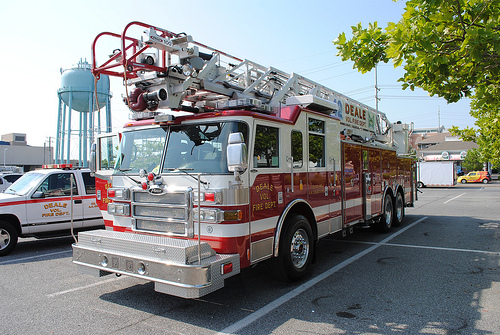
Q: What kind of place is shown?
A: It is a parking lot.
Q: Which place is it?
A: It is a parking lot.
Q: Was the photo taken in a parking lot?
A: Yes, it was taken in a parking lot.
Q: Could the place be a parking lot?
A: Yes, it is a parking lot.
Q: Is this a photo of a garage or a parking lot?
A: It is showing a parking lot.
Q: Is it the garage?
A: No, it is the parking lot.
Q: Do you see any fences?
A: No, there are no fences.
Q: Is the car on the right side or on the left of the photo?
A: The car is on the right of the image.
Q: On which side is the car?
A: The car is on the right of the image.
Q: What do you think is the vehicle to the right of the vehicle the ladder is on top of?
A: The vehicle is a car.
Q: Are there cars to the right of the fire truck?
A: Yes, there is a car to the right of the fire truck.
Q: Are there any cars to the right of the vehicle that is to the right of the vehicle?
A: Yes, there is a car to the right of the fire truck.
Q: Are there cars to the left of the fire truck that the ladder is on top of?
A: No, the car is to the right of the fire truck.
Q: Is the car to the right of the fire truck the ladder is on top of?
A: Yes, the car is to the right of the fire truck.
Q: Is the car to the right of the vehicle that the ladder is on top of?
A: Yes, the car is to the right of the fire truck.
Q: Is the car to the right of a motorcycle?
A: No, the car is to the right of the fire truck.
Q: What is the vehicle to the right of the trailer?
A: The vehicle is a car.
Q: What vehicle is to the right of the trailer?
A: The vehicle is a car.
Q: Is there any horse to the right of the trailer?
A: No, there is a car to the right of the trailer.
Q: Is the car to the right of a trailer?
A: Yes, the car is to the right of a trailer.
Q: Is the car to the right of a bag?
A: No, the car is to the right of a trailer.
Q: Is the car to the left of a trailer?
A: No, the car is to the right of a trailer.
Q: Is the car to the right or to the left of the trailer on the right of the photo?
A: The car is to the right of the trailer.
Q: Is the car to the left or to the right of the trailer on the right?
A: The car is to the right of the trailer.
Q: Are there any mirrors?
A: Yes, there is a mirror.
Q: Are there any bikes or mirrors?
A: Yes, there is a mirror.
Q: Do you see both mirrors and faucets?
A: No, there is a mirror but no faucets.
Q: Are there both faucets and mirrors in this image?
A: No, there is a mirror but no faucets.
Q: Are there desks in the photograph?
A: No, there are no desks.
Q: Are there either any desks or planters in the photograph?
A: No, there are no desks or planters.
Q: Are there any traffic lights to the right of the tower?
A: No, there is a mirror to the right of the tower.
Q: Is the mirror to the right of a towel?
A: No, the mirror is to the right of the tower.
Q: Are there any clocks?
A: No, there are no clocks.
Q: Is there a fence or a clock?
A: No, there are no clocks or fences.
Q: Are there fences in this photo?
A: No, there are no fences.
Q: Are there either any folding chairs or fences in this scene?
A: No, there are no fences or folding chairs.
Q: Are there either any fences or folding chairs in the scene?
A: No, there are no fences or folding chairs.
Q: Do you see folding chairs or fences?
A: No, there are no fences or folding chairs.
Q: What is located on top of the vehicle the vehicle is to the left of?
A: The ladder is on top of the fire truck.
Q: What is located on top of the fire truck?
A: The ladder is on top of the fire truck.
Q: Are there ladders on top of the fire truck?
A: Yes, there is a ladder on top of the fire truck.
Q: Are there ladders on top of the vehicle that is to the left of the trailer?
A: Yes, there is a ladder on top of the fire truck.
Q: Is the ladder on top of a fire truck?
A: Yes, the ladder is on top of a fire truck.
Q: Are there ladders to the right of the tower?
A: Yes, there is a ladder to the right of the tower.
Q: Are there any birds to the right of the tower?
A: No, there is a ladder to the right of the tower.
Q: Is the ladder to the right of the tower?
A: Yes, the ladder is to the right of the tower.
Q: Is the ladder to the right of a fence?
A: No, the ladder is to the right of the tower.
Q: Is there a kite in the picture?
A: No, there are no kites.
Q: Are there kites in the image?
A: No, there are no kites.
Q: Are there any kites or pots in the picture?
A: No, there are no kites or pots.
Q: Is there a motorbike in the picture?
A: No, there are no motorcycles.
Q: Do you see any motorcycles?
A: No, there are no motorcycles.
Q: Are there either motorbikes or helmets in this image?
A: No, there are no motorbikes or helmets.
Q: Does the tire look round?
A: Yes, the tire is round.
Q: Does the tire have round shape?
A: Yes, the tire is round.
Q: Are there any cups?
A: No, there are no cups.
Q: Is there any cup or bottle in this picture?
A: No, there are no cups or bottles.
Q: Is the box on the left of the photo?
A: Yes, the box is on the left of the image.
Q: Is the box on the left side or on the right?
A: The box is on the left of the image.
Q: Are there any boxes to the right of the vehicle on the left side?
A: Yes, there is a box to the right of the vehicle.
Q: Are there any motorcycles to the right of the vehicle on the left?
A: No, there is a box to the right of the vehicle.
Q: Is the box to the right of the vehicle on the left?
A: Yes, the box is to the right of the vehicle.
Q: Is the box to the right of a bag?
A: No, the box is to the right of the vehicle.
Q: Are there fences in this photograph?
A: No, there are no fences.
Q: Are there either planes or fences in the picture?
A: No, there are no fences or planes.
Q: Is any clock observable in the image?
A: No, there are no clocks.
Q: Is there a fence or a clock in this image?
A: No, there are no clocks or fences.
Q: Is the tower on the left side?
A: Yes, the tower is on the left of the image.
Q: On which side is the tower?
A: The tower is on the left of the image.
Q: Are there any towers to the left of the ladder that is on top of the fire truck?
A: Yes, there is a tower to the left of the ladder.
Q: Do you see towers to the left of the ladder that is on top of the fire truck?
A: Yes, there is a tower to the left of the ladder.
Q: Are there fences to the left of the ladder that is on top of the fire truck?
A: No, there is a tower to the left of the ladder.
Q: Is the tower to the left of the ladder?
A: Yes, the tower is to the left of the ladder.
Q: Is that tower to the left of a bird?
A: No, the tower is to the left of the ladder.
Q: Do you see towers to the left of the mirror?
A: Yes, there is a tower to the left of the mirror.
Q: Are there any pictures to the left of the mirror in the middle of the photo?
A: No, there is a tower to the left of the mirror.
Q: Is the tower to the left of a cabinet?
A: No, the tower is to the left of a mirror.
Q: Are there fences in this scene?
A: No, there are no fences.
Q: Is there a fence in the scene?
A: No, there are no fences.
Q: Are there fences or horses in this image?
A: No, there are no fences or horses.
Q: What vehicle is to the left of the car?
A: The vehicle is a trailer.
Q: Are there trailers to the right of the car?
A: No, the trailer is to the left of the car.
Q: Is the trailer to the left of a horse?
A: No, the trailer is to the left of the car.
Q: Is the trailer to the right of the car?
A: No, the trailer is to the left of the car.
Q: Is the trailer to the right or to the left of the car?
A: The trailer is to the left of the car.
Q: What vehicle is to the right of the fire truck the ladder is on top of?
A: The vehicle is a trailer.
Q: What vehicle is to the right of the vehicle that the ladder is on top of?
A: The vehicle is a trailer.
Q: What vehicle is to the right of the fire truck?
A: The vehicle is a trailer.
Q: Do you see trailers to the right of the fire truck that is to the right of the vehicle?
A: Yes, there is a trailer to the right of the fire truck.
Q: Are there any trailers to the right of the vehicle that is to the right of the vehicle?
A: Yes, there is a trailer to the right of the fire truck.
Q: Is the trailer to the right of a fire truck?
A: Yes, the trailer is to the right of a fire truck.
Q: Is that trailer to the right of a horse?
A: No, the trailer is to the right of a fire truck.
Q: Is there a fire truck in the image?
A: Yes, there is a fire truck.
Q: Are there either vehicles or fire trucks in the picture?
A: Yes, there is a fire truck.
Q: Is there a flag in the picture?
A: No, there are no flags.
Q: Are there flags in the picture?
A: No, there are no flags.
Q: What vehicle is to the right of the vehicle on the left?
A: The vehicle is a fire truck.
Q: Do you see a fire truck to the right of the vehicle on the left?
A: Yes, there is a fire truck to the right of the vehicle.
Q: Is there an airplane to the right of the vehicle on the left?
A: No, there is a fire truck to the right of the vehicle.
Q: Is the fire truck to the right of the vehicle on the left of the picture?
A: Yes, the fire truck is to the right of the vehicle.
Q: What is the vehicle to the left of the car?
A: The vehicle is a fire truck.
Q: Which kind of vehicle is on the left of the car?
A: The vehicle is a fire truck.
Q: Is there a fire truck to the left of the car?
A: Yes, there is a fire truck to the left of the car.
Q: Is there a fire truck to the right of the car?
A: No, the fire truck is to the left of the car.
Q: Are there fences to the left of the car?
A: No, there is a fire truck to the left of the car.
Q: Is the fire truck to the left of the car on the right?
A: Yes, the fire truck is to the left of the car.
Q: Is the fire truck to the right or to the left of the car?
A: The fire truck is to the left of the car.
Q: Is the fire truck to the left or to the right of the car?
A: The fire truck is to the left of the car.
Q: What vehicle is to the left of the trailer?
A: The vehicle is a fire truck.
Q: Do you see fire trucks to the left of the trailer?
A: Yes, there is a fire truck to the left of the trailer.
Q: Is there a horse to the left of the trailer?
A: No, there is a fire truck to the left of the trailer.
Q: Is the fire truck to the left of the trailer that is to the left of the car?
A: Yes, the fire truck is to the left of the trailer.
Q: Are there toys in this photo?
A: No, there are no toys.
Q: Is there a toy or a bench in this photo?
A: No, there are no toys or benches.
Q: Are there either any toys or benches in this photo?
A: No, there are no toys or benches.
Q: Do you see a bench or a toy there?
A: No, there are no toys or benches.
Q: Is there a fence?
A: No, there are no fences.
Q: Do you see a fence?
A: No, there are no fences.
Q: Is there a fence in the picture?
A: No, there are no fences.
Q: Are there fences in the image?
A: No, there are no fences.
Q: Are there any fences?
A: No, there are no fences.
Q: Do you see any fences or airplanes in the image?
A: No, there are no fences or airplanes.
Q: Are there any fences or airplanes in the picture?
A: No, there are no fences or airplanes.